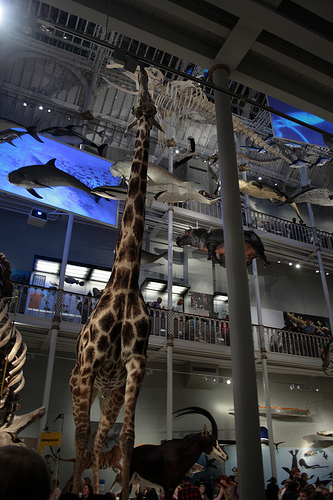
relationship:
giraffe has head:
[68, 69, 166, 500] [128, 62, 159, 120]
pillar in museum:
[208, 64, 265, 499] [1, 8, 330, 498]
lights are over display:
[35, 257, 230, 309] [25, 272, 228, 338]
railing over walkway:
[5, 280, 331, 358] [5, 311, 331, 378]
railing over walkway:
[177, 197, 333, 251] [1, 185, 332, 276]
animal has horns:
[123, 411, 227, 493] [171, 406, 218, 438]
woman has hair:
[214, 473, 236, 499] [216, 474, 233, 489]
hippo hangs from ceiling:
[175, 219, 272, 266] [47, 28, 332, 125]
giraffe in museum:
[82, 90, 172, 443] [23, 206, 316, 442]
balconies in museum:
[0, 42, 333, 377] [8, 37, 331, 396]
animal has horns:
[128, 406, 229, 499] [179, 402, 218, 444]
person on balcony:
[298, 318, 316, 336] [28, 286, 331, 358]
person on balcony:
[30, 283, 37, 312] [28, 286, 331, 358]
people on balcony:
[77, 292, 230, 345] [28, 286, 331, 358]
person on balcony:
[284, 216, 296, 233] [28, 286, 331, 358]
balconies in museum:
[142, 190, 330, 365] [1, 8, 330, 498]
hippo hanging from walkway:
[176, 226, 271, 269] [115, 194, 322, 273]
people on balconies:
[72, 279, 245, 347] [0, 42, 333, 377]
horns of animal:
[170, 403, 219, 437] [120, 400, 229, 498]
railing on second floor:
[8, 280, 330, 359] [5, 273, 331, 366]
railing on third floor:
[128, 183, 332, 269] [153, 179, 331, 264]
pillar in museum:
[212, 68, 265, 499] [1, 8, 330, 498]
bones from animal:
[102, 58, 292, 164] [8, 152, 151, 228]